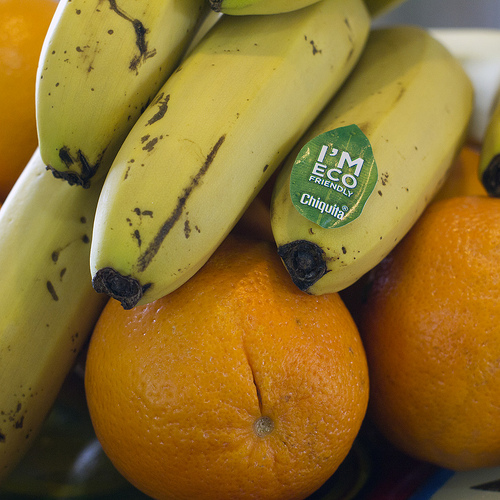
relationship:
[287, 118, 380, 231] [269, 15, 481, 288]
sticker of banana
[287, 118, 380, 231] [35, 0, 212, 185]
sticker of banana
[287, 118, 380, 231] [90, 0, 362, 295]
sticker of banana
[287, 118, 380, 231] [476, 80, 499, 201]
sticker of banana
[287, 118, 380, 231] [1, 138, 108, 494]
sticker of banana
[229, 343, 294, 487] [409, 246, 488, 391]
creases of orange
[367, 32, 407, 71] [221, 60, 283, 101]
shadow on skin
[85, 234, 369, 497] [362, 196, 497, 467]
fruit underneath fruit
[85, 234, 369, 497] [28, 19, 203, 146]
fruit underneath banana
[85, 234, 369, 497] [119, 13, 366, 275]
fruit underneath banana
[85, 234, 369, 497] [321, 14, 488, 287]
fruit underneath banana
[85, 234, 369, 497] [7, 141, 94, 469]
fruit underneath banana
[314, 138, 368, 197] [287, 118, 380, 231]
lettering on sticker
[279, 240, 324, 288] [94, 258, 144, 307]
end of end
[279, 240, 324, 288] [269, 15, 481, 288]
end of banana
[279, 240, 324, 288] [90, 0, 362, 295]
end of banana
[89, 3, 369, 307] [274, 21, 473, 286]
fruit behind fruit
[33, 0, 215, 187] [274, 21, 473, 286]
fruit behind fruit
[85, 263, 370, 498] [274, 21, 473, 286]
fruit behind fruit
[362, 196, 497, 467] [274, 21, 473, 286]
fruit behind fruit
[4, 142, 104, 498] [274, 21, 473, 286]
fruit behind fruit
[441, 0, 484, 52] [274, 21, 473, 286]
background behind fruit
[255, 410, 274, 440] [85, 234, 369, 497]
navel on fruit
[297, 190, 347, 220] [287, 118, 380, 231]
word on sticker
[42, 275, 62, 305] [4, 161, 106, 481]
spot on banana